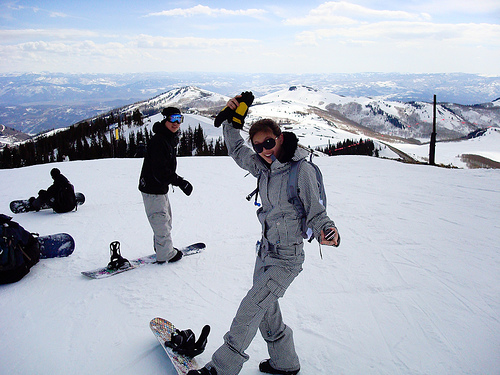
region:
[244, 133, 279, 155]
woman's black ski goggles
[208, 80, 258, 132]
black and yellow gloves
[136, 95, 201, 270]
man standing on a snowboard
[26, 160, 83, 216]
person sitting on the snow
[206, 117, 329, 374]
woman's grey snow suit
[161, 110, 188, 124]
goggles on a man's head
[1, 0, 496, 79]
blue sky with clouds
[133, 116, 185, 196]
man's black ski jacket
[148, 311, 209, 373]
woman's snow board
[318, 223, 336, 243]
electronic device in the woman's hand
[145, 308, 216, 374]
snowboard with foot straps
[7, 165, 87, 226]
person sitting on the ground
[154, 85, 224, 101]
snowy white mountain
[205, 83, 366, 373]
woman posing for the picture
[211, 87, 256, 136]
gloves in the hand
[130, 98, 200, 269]
person wearing black jacket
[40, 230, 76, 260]
part of a blue snowboard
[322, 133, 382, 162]
trees down over the hill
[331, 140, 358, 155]
red in the trees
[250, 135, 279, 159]
glasses on the woman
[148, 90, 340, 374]
A girl on a snow board.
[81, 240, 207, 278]
A snow board on the snow.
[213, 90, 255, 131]
A pair of gloves.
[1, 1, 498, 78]
Clouds in the sky.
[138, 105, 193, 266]
A man in the snow.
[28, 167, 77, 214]
A man sitting down.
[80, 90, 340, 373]
Two people on a mountain.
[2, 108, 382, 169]
Pine trees on a mountain.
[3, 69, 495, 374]
Snow on top of mountains.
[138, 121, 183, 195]
A black snow jacket.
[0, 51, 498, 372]
People are on a snowy hill.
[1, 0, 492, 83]
Clouds are in the sky.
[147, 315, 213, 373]
The woman has her foot on a snowboard.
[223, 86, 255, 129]
The woman is holding a yellow object.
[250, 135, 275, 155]
The woman is wearing sunglasses.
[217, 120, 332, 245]
The woman is wearing a grey jacket.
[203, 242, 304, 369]
The woman is wearing grey snow pants.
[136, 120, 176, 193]
The man is wearing a black jacket.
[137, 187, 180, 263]
The man is wearing grey snow pants.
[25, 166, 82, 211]
A person is sitting on the snow.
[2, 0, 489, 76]
light blue sky with clouds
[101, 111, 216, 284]
man on snow board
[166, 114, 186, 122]
goggles on man on snowboard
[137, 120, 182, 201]
black jacket on snowboarder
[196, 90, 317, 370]
person in grey ski suit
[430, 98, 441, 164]
tree trunk in snow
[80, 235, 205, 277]
snow board man is riding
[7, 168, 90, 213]
person sitting in snow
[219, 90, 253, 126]
container in persons hand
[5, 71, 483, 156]
mountains behind snowy hill